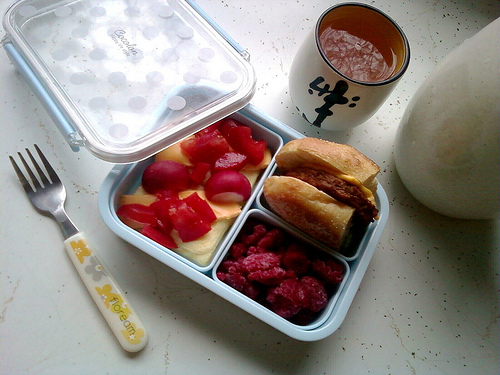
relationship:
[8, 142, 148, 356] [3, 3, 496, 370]
fork laying on table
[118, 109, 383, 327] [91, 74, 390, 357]
food inside dish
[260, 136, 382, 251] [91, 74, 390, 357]
sandwich inside of dish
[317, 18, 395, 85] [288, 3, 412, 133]
chocolate inside of cup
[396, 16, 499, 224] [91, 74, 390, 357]
jar beside of dish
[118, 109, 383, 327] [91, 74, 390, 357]
food inside of dish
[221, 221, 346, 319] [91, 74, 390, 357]
strawberries inside of dish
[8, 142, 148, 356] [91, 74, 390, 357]
fork beside of dish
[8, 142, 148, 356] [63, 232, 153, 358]
fork has a handle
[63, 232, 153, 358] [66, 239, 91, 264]
handle has flower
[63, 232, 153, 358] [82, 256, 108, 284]
handle has flower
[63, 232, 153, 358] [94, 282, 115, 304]
handle has flower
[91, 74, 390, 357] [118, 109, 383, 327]
dish contains food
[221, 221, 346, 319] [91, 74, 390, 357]
strawberries are inside of dish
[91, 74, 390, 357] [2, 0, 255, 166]
dish has a top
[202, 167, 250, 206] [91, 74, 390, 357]
radish inside of dish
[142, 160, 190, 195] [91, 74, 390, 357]
radish inside of dish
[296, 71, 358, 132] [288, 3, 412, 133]
image on cup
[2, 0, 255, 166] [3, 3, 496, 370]
top on top of table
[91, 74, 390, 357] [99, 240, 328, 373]
dish has a shadow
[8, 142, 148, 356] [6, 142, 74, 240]
fork has fork prongs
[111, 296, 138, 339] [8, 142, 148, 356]
letters are on fork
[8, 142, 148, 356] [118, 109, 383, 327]
fork beside of food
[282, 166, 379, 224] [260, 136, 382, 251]
meat on sandwich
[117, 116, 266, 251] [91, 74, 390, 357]
vegetables are inside of dish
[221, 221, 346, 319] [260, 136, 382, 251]
strawberries beside of sandwich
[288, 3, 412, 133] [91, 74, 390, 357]
cup beside of dish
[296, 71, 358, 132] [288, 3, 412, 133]
image on side of th cup